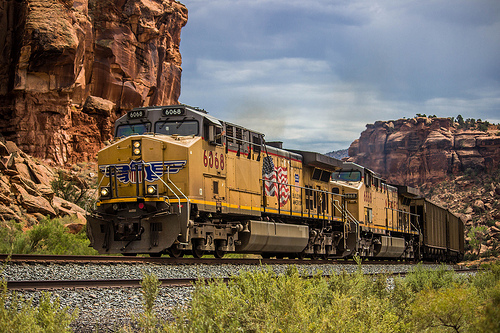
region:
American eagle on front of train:
[97, 145, 198, 234]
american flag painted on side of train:
[261, 150, 315, 222]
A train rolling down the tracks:
[90, 108, 475, 300]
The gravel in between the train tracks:
[9, 257, 473, 304]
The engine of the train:
[102, 113, 357, 258]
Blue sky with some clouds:
[196, 18, 481, 127]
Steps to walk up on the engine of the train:
[271, 178, 364, 261]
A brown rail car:
[415, 187, 479, 262]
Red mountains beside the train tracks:
[7, 1, 191, 138]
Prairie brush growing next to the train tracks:
[146, 278, 472, 332]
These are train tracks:
[45, 247, 159, 302]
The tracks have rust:
[19, 250, 177, 326]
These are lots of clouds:
[250, 33, 406, 120]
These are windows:
[84, 122, 187, 139]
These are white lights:
[84, 188, 204, 211]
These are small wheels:
[139, 242, 315, 256]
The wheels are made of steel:
[162, 247, 206, 259]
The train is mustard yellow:
[107, 100, 317, 236]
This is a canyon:
[46, 67, 105, 130]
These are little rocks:
[99, 291, 133, 313]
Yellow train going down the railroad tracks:
[81, 103, 419, 259]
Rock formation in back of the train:
[344, 112, 498, 251]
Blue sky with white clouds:
[178, 0, 498, 155]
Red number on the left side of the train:
[196, 143, 227, 174]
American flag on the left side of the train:
[260, 153, 293, 203]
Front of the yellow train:
[90, 100, 208, 251]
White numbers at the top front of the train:
[160, 105, 181, 120]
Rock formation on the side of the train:
[0, 0, 190, 222]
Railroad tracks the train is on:
[1, 250, 496, 290]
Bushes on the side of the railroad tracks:
[1, 267, 498, 332]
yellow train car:
[105, 118, 406, 245]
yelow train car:
[300, 162, 397, 244]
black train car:
[404, 199, 472, 250]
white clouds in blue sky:
[202, 3, 252, 65]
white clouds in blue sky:
[195, 46, 239, 97]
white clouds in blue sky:
[231, 36, 269, 91]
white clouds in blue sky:
[261, 61, 302, 126]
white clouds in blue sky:
[287, 58, 341, 119]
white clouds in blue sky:
[337, 3, 398, 67]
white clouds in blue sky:
[384, 51, 439, 88]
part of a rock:
[50, 203, 60, 222]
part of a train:
[171, 141, 195, 179]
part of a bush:
[308, 288, 318, 300]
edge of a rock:
[66, 115, 69, 126]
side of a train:
[309, 180, 329, 195]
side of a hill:
[426, 152, 428, 167]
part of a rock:
[88, 264, 95, 269]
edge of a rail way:
[72, 248, 84, 256]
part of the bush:
[353, 275, 360, 293]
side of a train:
[286, 185, 291, 197]